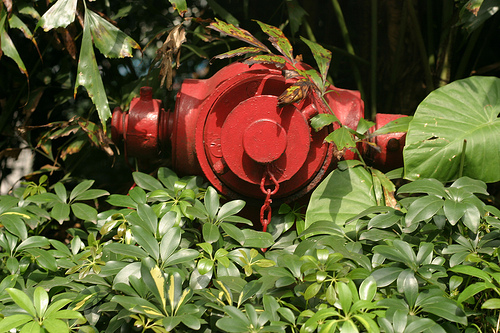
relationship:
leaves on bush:
[32, 177, 106, 227] [2, 165, 497, 332]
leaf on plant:
[401, 272, 420, 309] [24, 150, 299, 307]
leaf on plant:
[371, 267, 400, 286] [0, 170, 497, 331]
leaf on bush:
[366, 236, 416, 271] [0, 183, 499, 332]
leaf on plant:
[219, 196, 246, 216] [179, 184, 256, 246]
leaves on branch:
[366, 231, 447, 306] [396, 181, 484, 313]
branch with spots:
[206, 14, 371, 154] [282, 90, 307, 102]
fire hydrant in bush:
[101, 53, 423, 223] [0, 183, 499, 332]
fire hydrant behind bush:
[101, 53, 424, 237] [3, 185, 485, 329]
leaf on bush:
[398, 177, 453, 197] [0, 183, 499, 332]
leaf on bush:
[443, 197, 467, 224] [0, 183, 499, 332]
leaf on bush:
[448, 177, 488, 192] [0, 183, 499, 332]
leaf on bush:
[365, 210, 402, 227] [0, 183, 499, 332]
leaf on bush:
[416, 242, 432, 259] [0, 183, 499, 332]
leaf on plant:
[394, 179, 451, 201] [0, 170, 497, 331]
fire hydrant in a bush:
[101, 53, 424, 237] [0, 0, 500, 330]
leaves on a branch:
[268, 224, 384, 303] [221, 61, 452, 202]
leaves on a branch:
[90, 205, 245, 313] [0, 166, 498, 327]